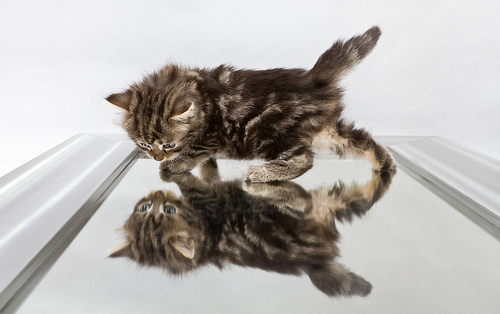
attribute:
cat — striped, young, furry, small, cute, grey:
[106, 26, 400, 175]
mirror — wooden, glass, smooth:
[4, 144, 499, 313]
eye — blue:
[162, 138, 183, 153]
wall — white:
[0, 1, 499, 166]